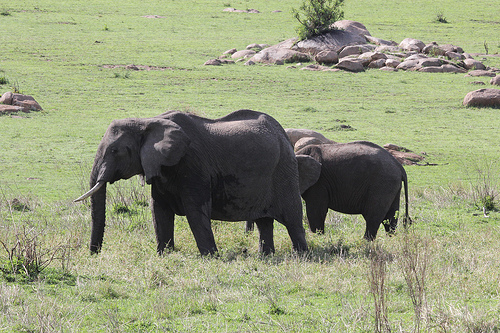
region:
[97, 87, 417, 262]
elephants standing on grass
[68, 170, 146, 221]
elephant has white tusk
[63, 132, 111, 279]
elephant has long trunk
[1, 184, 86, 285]
green bush in front of elephant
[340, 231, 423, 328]
small and bare bushy tree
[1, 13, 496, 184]
short green grass on field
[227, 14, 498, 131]
rock outcropping behind elephants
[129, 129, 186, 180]
elephant has large ears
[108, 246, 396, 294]
taller grass near elephant's feet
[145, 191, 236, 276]
elephant has dark grey legs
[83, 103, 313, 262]
Elephant in the front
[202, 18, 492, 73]
Row of rocks in the upper corner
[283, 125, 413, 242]
Elephant in the back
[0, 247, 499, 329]
Grass beneath the elephants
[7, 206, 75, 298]
grass tufts on the left corner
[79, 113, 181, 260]
Elephant head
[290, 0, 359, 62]
Plant on top of the rocks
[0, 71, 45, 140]
Rocks near the left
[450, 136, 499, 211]
grass tuft on the right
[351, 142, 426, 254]
Elephant tail of the elephant in the back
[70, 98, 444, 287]
elephants in the pasture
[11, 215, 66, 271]
bare bush in the grass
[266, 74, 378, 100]
green grass near elephants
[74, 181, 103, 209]
tusk of an elephant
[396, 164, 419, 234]
tail of an elephant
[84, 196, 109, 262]
trunk of an elephant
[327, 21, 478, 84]
boulders in the grass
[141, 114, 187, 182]
left ear of an elephant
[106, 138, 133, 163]
left eye of an elephant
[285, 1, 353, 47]
green bush in the rocks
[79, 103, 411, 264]
elephants walking in a field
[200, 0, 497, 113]
rocks in a meadow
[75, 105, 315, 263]
mother elephant in a field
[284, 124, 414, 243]
small elephant in a field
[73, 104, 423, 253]
mother elephant with her child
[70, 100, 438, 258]
small elephant following mother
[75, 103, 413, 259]
small elephant hiding behind another elephant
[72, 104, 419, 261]
elephants wandering through the savanna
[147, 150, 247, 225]
discoloration on an elephant's chest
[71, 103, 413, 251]
elephants migrating to find food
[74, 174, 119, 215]
long elephant white tusk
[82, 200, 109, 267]
elephants trunk in the grass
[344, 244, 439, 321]
dead weeds in the grass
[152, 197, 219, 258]
elephants large front legs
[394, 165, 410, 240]
elephants long grey tail pointing down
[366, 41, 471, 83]
large rocks on the grass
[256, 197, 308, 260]
elephants big grey back legs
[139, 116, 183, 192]
elephant large grey left ear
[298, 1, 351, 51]
small shrub on top of mound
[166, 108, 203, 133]
hump on the elephants back